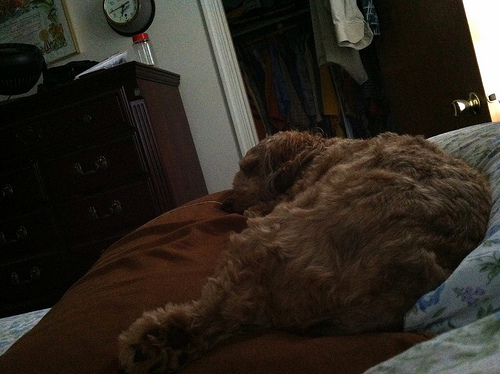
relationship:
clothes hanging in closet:
[246, 0, 383, 155] [215, 0, 491, 141]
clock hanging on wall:
[104, 1, 158, 36] [55, 0, 243, 191]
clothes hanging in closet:
[254, 46, 428, 154] [215, 0, 491, 141]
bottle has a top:
[131, 32, 160, 68] [129, 27, 149, 43]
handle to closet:
[451, 94, 483, 119] [359, 2, 491, 135]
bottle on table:
[123, 32, 168, 67] [0, 67, 202, 141]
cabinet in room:
[0, 59, 207, 316] [3, 5, 496, 371]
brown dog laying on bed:
[115, 130, 494, 374] [2, 117, 499, 371]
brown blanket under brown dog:
[0, 190, 428, 370] [115, 130, 494, 374]